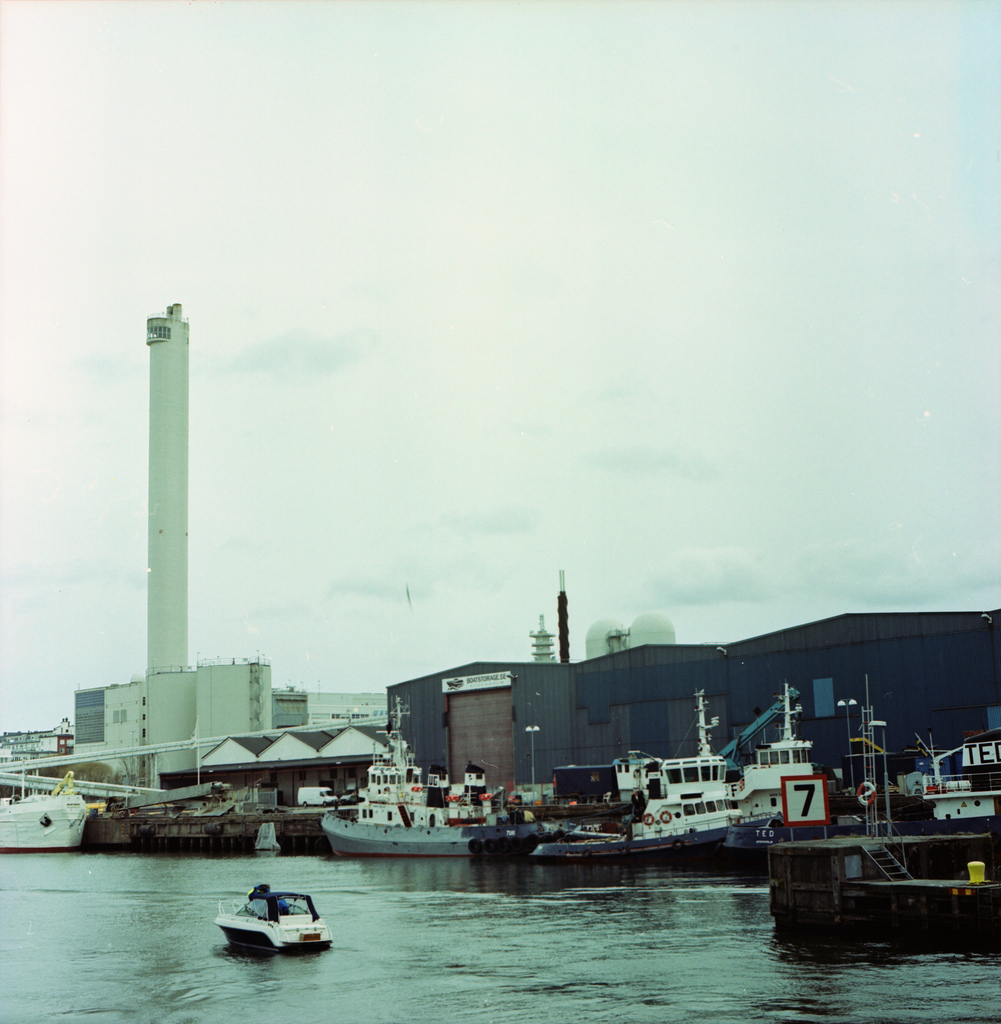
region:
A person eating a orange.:
[549, 646, 634, 891]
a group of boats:
[10, 696, 833, 876]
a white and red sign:
[774, 761, 836, 832]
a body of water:
[25, 825, 864, 1022]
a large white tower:
[142, 301, 199, 711]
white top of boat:
[347, 752, 438, 826]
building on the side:
[367, 596, 999, 780]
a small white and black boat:
[202, 869, 342, 961]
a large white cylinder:
[173, 652, 288, 747]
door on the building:
[434, 673, 532, 790]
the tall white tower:
[141, 302, 192, 673]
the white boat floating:
[207, 882, 337, 956]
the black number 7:
[792, 779, 819, 820]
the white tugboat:
[316, 742, 490, 854]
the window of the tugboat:
[669, 763, 689, 783]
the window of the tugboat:
[680, 756, 701, 781]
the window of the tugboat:
[696, 799, 708, 816]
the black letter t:
[965, 738, 983, 768]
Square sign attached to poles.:
[771, 771, 836, 832]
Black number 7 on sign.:
[780, 768, 822, 828]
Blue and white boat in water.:
[208, 882, 338, 970]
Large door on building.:
[442, 682, 514, 787]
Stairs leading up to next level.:
[871, 837, 908, 887]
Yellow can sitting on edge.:
[957, 849, 997, 886]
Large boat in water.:
[338, 784, 522, 871]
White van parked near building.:
[296, 775, 341, 806]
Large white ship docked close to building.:
[6, 788, 108, 868]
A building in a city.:
[75, 662, 270, 736]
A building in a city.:
[529, 617, 549, 658]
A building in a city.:
[587, 614, 659, 651]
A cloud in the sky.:
[442, 506, 560, 553]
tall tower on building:
[131, 302, 201, 675]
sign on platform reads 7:
[778, 761, 832, 835]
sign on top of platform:
[772, 768, 830, 833]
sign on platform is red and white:
[773, 770, 828, 831]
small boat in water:
[211, 871, 335, 958]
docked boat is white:
[0, 764, 88, 854]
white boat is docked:
[3, 763, 94, 864]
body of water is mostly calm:
[3, 834, 999, 1022]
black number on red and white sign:
[771, 770, 873, 855]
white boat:
[298, 757, 469, 872]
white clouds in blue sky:
[610, 216, 747, 359]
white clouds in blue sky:
[362, 359, 452, 456]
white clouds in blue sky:
[62, 118, 137, 175]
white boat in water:
[221, 864, 349, 954]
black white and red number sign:
[771, 766, 845, 846]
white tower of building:
[108, 269, 212, 652]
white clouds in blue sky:
[228, 165, 285, 205]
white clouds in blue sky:
[397, 355, 495, 460]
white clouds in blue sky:
[387, 277, 487, 381]